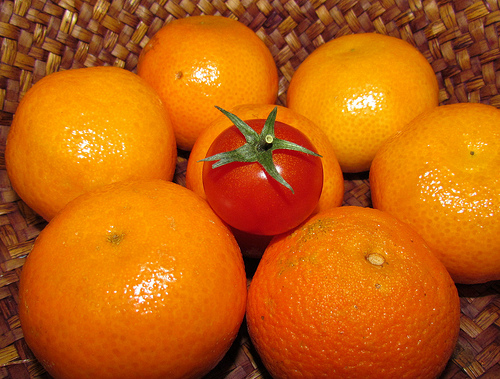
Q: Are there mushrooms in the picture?
A: No, there are no mushrooms.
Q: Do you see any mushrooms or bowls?
A: No, there are no mushrooms or bowls.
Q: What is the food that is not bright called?
A: The food is a tomato.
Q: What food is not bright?
A: The food is a tomato.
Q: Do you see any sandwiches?
A: No, there are no sandwiches.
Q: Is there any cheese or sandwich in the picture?
A: No, there are no sandwiches or cheese.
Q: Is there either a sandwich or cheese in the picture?
A: No, there are no sandwiches or cheese.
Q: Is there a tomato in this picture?
A: Yes, there is a tomato.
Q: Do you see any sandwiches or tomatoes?
A: Yes, there is a tomato.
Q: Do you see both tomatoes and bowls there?
A: No, there is a tomato but no bowls.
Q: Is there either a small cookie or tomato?
A: Yes, there is a small tomato.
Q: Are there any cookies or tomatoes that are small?
A: Yes, the tomato is small.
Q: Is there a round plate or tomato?
A: Yes, there is a round tomato.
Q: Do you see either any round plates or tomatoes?
A: Yes, there is a round tomato.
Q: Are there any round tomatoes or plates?
A: Yes, there is a round tomato.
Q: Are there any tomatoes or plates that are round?
A: Yes, the tomato is round.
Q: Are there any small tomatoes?
A: Yes, there is a small tomato.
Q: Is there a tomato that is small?
A: Yes, there is a tomato that is small.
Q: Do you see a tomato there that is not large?
A: Yes, there is a small tomato.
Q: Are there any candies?
A: No, there are no candies.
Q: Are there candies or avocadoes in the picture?
A: No, there are no candies or avocadoes.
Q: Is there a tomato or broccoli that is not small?
A: No, there is a tomato but it is small.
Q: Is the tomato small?
A: Yes, the tomato is small.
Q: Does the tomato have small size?
A: Yes, the tomato is small.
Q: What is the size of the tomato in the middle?
A: The tomato is small.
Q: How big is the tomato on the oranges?
A: The tomato is small.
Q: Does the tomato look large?
A: No, the tomato is small.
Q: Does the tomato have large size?
A: No, the tomato is small.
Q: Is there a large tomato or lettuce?
A: No, there is a tomato but it is small.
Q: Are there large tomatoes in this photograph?
A: No, there is a tomato but it is small.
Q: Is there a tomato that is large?
A: No, there is a tomato but it is small.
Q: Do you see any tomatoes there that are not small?
A: No, there is a tomato but it is small.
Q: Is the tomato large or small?
A: The tomato is small.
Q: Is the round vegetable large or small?
A: The tomato is small.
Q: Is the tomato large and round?
A: No, the tomato is round but small.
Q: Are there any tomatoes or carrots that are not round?
A: No, there is a tomato but it is round.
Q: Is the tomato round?
A: Yes, the tomato is round.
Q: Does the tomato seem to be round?
A: Yes, the tomato is round.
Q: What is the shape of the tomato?
A: The tomato is round.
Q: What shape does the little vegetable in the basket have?
A: The tomato has round shape.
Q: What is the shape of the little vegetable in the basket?
A: The tomato is round.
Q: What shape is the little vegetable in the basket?
A: The tomato is round.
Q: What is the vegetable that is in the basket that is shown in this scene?
A: The vegetable is a tomato.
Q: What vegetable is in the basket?
A: The vegetable is a tomato.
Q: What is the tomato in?
A: The tomato is in the basket.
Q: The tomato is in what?
A: The tomato is in the basket.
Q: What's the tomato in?
A: The tomato is in the basket.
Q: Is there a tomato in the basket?
A: Yes, there is a tomato in the basket.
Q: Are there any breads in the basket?
A: No, there is a tomato in the basket.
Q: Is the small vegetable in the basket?
A: Yes, the tomato is in the basket.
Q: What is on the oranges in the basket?
A: The tomato is on the oranges.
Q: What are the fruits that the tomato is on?
A: The fruits are oranges.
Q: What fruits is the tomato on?
A: The tomato is on the oranges.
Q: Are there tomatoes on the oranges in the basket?
A: Yes, there is a tomato on the oranges.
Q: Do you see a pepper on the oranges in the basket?
A: No, there is a tomato on the oranges.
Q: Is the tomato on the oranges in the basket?
A: Yes, the tomato is on the oranges.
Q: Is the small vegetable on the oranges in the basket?
A: Yes, the tomato is on the oranges.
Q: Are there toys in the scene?
A: No, there are no toys.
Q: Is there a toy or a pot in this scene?
A: No, there are no toys or pots.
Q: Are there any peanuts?
A: No, there are no peanuts.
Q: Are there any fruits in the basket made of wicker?
A: Yes, there are fruits in the basket.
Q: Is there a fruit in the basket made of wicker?
A: Yes, there are fruits in the basket.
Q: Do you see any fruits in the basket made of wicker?
A: Yes, there are fruits in the basket.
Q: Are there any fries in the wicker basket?
A: No, there are fruits in the basket.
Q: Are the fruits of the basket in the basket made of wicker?
A: Yes, the fruits are in the basket.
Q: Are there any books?
A: No, there are no books.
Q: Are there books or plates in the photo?
A: No, there are no books or plates.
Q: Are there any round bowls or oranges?
A: Yes, there are round oranges.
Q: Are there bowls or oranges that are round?
A: Yes, the oranges are round.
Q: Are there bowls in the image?
A: No, there are no bowls.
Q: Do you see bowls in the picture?
A: No, there are no bowls.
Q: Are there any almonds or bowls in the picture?
A: No, there are no bowls or almonds.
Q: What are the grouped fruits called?
A: The fruits are oranges.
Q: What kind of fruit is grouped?
A: The fruit is oranges.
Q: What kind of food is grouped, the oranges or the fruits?
A: The oranges is grouped.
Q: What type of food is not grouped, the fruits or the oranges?
A: The fruits is not grouped.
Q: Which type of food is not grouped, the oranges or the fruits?
A: The fruits is not grouped.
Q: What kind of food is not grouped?
A: The food is fruits.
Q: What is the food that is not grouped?
A: The food is fruits.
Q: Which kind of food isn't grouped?
A: The food is fruits.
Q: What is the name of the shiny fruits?
A: The fruits are oranges.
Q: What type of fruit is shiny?
A: The fruit is oranges.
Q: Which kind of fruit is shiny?
A: The fruit is oranges.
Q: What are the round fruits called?
A: The fruits are oranges.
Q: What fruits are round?
A: The fruits are oranges.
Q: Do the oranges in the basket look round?
A: Yes, the oranges are round.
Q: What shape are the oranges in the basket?
A: The oranges are round.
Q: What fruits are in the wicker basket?
A: The fruits are oranges.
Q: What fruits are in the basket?
A: The fruits are oranges.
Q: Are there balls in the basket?
A: No, there are oranges in the basket.